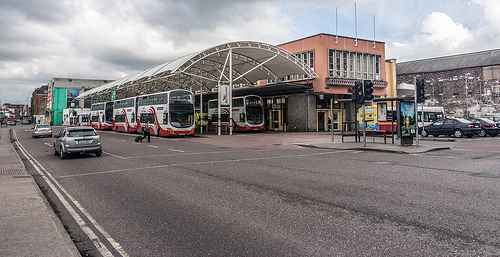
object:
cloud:
[69, 22, 193, 72]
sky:
[307, 13, 338, 29]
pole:
[331, 6, 340, 40]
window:
[329, 50, 335, 79]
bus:
[137, 87, 197, 138]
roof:
[47, 77, 118, 89]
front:
[168, 89, 194, 131]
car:
[49, 123, 107, 162]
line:
[40, 169, 93, 227]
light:
[354, 82, 365, 90]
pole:
[360, 104, 367, 148]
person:
[132, 119, 154, 143]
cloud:
[0, 12, 77, 63]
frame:
[217, 49, 237, 84]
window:
[247, 96, 263, 123]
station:
[273, 31, 391, 132]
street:
[310, 152, 409, 180]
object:
[377, 121, 398, 133]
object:
[53, 82, 67, 125]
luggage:
[134, 134, 143, 143]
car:
[419, 115, 484, 138]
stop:
[303, 134, 342, 147]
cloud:
[144, 5, 240, 33]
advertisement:
[355, 105, 376, 129]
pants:
[140, 131, 154, 144]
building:
[35, 95, 48, 116]